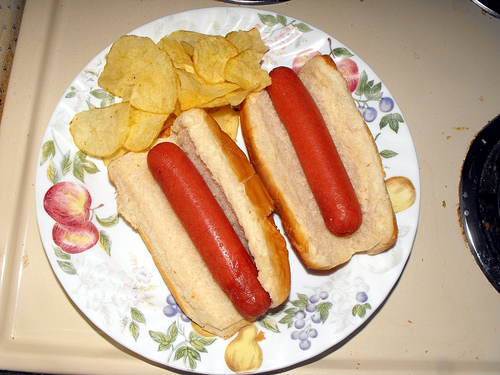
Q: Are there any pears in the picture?
A: Yes, there is a pear.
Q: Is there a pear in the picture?
A: Yes, there is a pear.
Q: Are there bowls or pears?
A: Yes, there is a pear.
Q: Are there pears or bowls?
A: Yes, there is a pear.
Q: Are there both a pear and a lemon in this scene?
A: No, there is a pear but no lemons.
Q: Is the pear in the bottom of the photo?
A: Yes, the pear is in the bottom of the image.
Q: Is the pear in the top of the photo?
A: No, the pear is in the bottom of the image.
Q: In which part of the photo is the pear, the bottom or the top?
A: The pear is in the bottom of the image.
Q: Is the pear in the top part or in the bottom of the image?
A: The pear is in the bottom of the image.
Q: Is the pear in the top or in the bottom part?
A: The pear is in the bottom of the image.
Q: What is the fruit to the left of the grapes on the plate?
A: The fruit is a pear.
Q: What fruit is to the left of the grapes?
A: The fruit is a pear.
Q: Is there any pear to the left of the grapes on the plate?
A: Yes, there is a pear to the left of the grapes.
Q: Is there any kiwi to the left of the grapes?
A: No, there is a pear to the left of the grapes.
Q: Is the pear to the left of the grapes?
A: Yes, the pear is to the left of the grapes.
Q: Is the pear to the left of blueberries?
A: No, the pear is to the left of the grapes.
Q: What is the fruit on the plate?
A: The fruit is a pear.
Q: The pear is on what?
A: The pear is on the plate.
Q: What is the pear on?
A: The pear is on the plate.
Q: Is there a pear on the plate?
A: Yes, there is a pear on the plate.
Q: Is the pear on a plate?
A: Yes, the pear is on a plate.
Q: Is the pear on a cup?
A: No, the pear is on a plate.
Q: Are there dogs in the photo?
A: Yes, there is a dog.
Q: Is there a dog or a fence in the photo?
A: Yes, there is a dog.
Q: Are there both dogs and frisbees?
A: No, there is a dog but no frisbees.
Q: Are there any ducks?
A: No, there are no ducks.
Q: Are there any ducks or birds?
A: No, there are no ducks or birds.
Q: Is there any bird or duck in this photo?
A: No, there are no ducks or birds.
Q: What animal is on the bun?
A: The dog is on the bun.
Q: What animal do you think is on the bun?
A: The animal is a dog.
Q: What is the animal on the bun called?
A: The animal is a dog.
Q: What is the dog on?
A: The dog is on the bun.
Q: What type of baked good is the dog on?
A: The dog is on the bun.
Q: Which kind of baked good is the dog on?
A: The dog is on the bun.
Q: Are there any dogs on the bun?
A: Yes, there is a dog on the bun.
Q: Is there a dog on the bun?
A: Yes, there is a dog on the bun.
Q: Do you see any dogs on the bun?
A: Yes, there is a dog on the bun.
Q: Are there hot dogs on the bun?
A: No, there is a dog on the bun.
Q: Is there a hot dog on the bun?
A: No, there is a dog on the bun.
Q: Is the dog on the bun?
A: Yes, the dog is on the bun.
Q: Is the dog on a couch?
A: No, the dog is on the bun.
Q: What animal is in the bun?
A: The dog is in the bun.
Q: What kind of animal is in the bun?
A: The animal is a dog.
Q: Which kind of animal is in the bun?
A: The animal is a dog.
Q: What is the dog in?
A: The dog is in the bun.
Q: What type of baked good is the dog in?
A: The dog is in the bun.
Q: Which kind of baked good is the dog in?
A: The dog is in the bun.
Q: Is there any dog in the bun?
A: Yes, there is a dog in the bun.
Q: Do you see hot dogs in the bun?
A: No, there is a dog in the bun.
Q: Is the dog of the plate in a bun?
A: Yes, the dog is in a bun.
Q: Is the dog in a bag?
A: No, the dog is in a bun.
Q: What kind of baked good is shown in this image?
A: The baked good is a bun.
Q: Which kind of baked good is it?
A: The food is a bun.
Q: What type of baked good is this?
A: That is a bun.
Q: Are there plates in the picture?
A: Yes, there is a plate.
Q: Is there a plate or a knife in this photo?
A: Yes, there is a plate.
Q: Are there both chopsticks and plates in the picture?
A: No, there is a plate but no chopsticks.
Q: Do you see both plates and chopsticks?
A: No, there is a plate but no chopsticks.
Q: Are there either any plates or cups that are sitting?
A: Yes, the plate is sitting.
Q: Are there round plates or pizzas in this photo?
A: Yes, there is a round plate.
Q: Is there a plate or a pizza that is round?
A: Yes, the plate is round.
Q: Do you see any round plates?
A: Yes, there is a round plate.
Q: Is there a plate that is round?
A: Yes, there is a plate that is round.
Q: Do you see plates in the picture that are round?
A: Yes, there is a plate that is round.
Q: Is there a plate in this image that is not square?
A: Yes, there is a round plate.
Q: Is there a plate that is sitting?
A: Yes, there is a plate that is sitting.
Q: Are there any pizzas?
A: No, there are no pizzas.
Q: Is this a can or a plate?
A: This is a plate.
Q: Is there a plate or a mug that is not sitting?
A: No, there is a plate but it is sitting.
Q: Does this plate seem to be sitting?
A: Yes, the plate is sitting.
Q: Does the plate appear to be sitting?
A: Yes, the plate is sitting.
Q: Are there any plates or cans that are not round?
A: No, there is a plate but it is round.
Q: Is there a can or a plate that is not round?
A: No, there is a plate but it is round.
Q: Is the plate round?
A: Yes, the plate is round.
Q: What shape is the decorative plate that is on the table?
A: The plate is round.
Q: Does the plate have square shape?
A: No, the plate is round.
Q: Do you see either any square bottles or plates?
A: No, there is a plate but it is round.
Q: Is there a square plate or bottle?
A: No, there is a plate but it is round.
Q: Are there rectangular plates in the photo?
A: No, there is a plate but it is round.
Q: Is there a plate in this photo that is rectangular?
A: No, there is a plate but it is round.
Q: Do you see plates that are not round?
A: No, there is a plate but it is round.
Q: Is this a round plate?
A: Yes, this is a round plate.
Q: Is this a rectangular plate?
A: No, this is a round plate.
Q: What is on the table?
A: The plate is on the table.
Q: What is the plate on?
A: The plate is on the table.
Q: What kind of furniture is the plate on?
A: The plate is on the table.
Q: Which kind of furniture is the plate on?
A: The plate is on the table.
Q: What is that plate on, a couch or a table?
A: The plate is on a table.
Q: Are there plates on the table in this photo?
A: Yes, there is a plate on the table.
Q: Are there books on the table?
A: No, there is a plate on the table.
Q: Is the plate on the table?
A: Yes, the plate is on the table.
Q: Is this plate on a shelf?
A: No, the plate is on the table.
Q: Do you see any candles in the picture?
A: No, there are no candles.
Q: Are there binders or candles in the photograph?
A: No, there are no candles or binders.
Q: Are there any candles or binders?
A: No, there are no candles or binders.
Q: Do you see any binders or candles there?
A: No, there are no candles or binders.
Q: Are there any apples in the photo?
A: Yes, there is an apple.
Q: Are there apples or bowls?
A: Yes, there is an apple.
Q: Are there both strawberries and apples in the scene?
A: No, there is an apple but no strawberries.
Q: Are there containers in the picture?
A: No, there are no containers.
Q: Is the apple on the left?
A: Yes, the apple is on the left of the image.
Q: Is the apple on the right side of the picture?
A: No, the apple is on the left of the image.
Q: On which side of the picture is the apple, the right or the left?
A: The apple is on the left of the image.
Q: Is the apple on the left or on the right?
A: The apple is on the left of the image.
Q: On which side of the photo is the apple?
A: The apple is on the left of the image.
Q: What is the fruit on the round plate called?
A: The fruit is an apple.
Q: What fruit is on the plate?
A: The fruit is an apple.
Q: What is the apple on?
A: The apple is on the plate.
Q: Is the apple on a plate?
A: Yes, the apple is on a plate.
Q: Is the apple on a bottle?
A: No, the apple is on a plate.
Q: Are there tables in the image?
A: Yes, there is a table.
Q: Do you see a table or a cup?
A: Yes, there is a table.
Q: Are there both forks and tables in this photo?
A: No, there is a table but no forks.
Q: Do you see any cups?
A: No, there are no cups.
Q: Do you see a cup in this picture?
A: No, there are no cups.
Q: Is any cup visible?
A: No, there are no cups.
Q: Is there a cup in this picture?
A: No, there are no cups.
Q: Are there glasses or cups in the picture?
A: No, there are no cups or glasses.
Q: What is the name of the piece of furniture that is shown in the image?
A: The piece of furniture is a table.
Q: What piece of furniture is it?
A: The piece of furniture is a table.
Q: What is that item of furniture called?
A: This is a table.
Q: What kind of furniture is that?
A: This is a table.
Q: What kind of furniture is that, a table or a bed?
A: This is a table.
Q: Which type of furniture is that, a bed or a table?
A: This is a table.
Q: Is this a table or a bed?
A: This is a table.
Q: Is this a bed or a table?
A: This is a table.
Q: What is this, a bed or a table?
A: This is a table.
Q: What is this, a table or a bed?
A: This is a table.